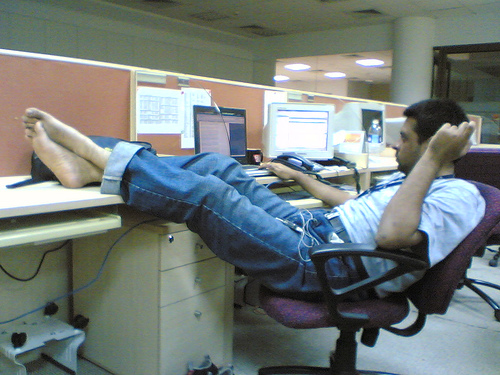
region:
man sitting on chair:
[12, 77, 499, 343]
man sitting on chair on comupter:
[17, 94, 499, 359]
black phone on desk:
[272, 141, 348, 205]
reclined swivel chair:
[228, 154, 498, 374]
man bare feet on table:
[14, 85, 146, 227]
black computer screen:
[192, 90, 259, 157]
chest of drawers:
[35, 208, 262, 373]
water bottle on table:
[364, 111, 395, 190]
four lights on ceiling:
[272, 50, 396, 102]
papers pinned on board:
[125, 77, 232, 164]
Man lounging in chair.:
[17, 95, 494, 337]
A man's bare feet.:
[8, 97, 103, 186]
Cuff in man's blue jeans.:
[98, 138, 149, 200]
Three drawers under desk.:
[97, 221, 242, 374]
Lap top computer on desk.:
[189, 99, 276, 176]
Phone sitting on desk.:
[268, 147, 329, 181]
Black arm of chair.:
[307, 242, 426, 320]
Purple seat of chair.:
[263, 294, 415, 338]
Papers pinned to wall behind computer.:
[138, 81, 215, 151]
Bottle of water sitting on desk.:
[363, 114, 392, 168]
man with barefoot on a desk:
[5, 83, 170, 242]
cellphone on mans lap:
[270, 194, 340, 267]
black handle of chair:
[300, 231, 463, 333]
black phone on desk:
[268, 143, 333, 181]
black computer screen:
[182, 97, 279, 172]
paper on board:
[125, 75, 277, 150]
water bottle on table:
[363, 113, 388, 181]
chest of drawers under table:
[75, 190, 258, 374]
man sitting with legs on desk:
[0, 70, 499, 352]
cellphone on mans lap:
[270, 192, 337, 282]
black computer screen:
[171, 96, 261, 166]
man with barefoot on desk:
[13, 90, 178, 225]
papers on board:
[129, 79, 247, 154]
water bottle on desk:
[347, 116, 392, 183]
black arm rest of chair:
[298, 235, 454, 332]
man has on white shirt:
[338, 163, 493, 302]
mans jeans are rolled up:
[98, 126, 165, 221]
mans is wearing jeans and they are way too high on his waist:
[95, 142, 370, 307]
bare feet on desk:
[22, 100, 118, 197]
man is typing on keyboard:
[237, 160, 273, 180]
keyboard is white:
[238, 162, 270, 180]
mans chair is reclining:
[252, 174, 499, 373]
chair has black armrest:
[307, 230, 427, 330]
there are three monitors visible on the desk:
[192, 85, 388, 177]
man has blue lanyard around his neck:
[347, 169, 461, 201]